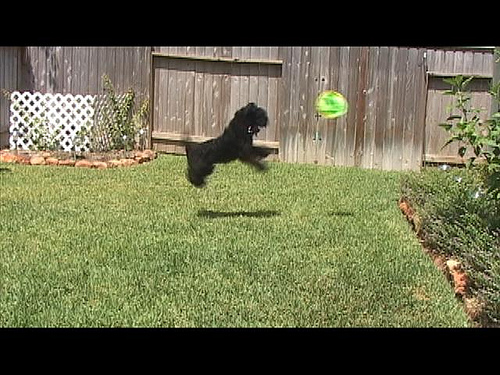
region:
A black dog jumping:
[178, 96, 283, 198]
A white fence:
[6, 88, 141, 158]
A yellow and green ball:
[312, 81, 352, 128]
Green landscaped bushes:
[391, 166, 498, 325]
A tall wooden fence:
[0, 47, 495, 162]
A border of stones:
[0, 144, 160, 173]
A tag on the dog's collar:
[238, 122, 264, 144]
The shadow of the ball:
[327, 206, 355, 220]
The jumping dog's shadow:
[194, 199, 281, 226]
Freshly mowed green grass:
[0, 163, 477, 327]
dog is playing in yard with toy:
[52, 70, 410, 236]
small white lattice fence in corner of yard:
[10, 82, 155, 152]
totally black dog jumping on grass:
[172, 86, 292, 206]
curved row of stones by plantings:
[2, 150, 157, 170]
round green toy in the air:
[310, 85, 355, 127]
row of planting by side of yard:
[390, 150, 495, 316]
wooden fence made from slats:
[176, 50, 406, 130]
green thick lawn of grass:
[60, 217, 395, 308]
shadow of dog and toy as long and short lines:
[170, 195, 377, 225]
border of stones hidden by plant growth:
[392, 185, 484, 320]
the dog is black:
[162, 85, 293, 215]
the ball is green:
[287, 53, 357, 137]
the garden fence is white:
[6, 63, 141, 171]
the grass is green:
[13, 147, 390, 323]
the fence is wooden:
[70, 45, 498, 182]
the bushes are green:
[400, 106, 499, 320]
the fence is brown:
[17, 44, 488, 169]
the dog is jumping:
[140, 78, 290, 220]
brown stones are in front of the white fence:
[2, 145, 159, 182]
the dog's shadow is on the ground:
[157, 86, 284, 261]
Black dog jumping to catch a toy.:
[176, 91, 352, 191]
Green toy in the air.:
[313, 86, 350, 121]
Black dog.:
[175, 99, 280, 191]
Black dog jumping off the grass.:
[171, 98, 286, 284]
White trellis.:
[6, 86, 143, 155]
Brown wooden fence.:
[1, 46, 498, 164]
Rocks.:
[0, 149, 157, 169]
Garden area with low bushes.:
[396, 73, 498, 325]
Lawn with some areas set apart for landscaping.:
[0, 73, 499, 325]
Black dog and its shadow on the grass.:
[177, 98, 286, 222]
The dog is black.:
[179, 114, 281, 176]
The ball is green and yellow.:
[310, 79, 347, 119]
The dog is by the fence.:
[174, 86, 273, 196]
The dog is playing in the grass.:
[170, 119, 290, 231]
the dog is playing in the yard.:
[166, 65, 382, 270]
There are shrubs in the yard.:
[380, 71, 495, 351]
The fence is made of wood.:
[170, 57, 232, 119]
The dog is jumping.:
[176, 107, 296, 242]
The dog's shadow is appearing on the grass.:
[172, 194, 357, 233]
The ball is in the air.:
[293, 73, 404, 164]